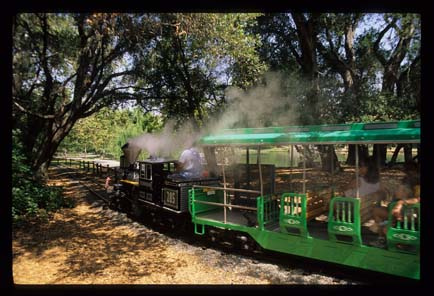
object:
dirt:
[12, 165, 359, 283]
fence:
[51, 157, 116, 177]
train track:
[56, 163, 113, 204]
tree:
[10, 13, 217, 186]